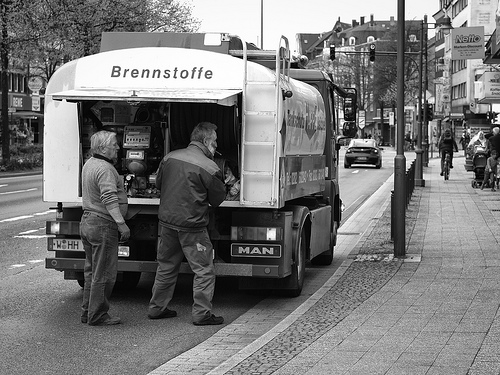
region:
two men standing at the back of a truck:
[24, 20, 368, 332]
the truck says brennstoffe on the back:
[25, 15, 357, 316]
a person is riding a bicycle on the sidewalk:
[429, 121, 467, 184]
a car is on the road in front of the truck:
[328, 115, 403, 187]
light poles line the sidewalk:
[382, 2, 452, 264]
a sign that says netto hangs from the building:
[423, 11, 499, 71]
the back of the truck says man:
[224, 202, 303, 286]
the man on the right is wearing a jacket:
[144, 119, 259, 339]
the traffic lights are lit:
[305, 36, 427, 71]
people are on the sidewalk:
[454, 120, 499, 221]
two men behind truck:
[24, 17, 372, 339]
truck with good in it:
[34, 7, 374, 324]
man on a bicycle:
[407, 119, 463, 192]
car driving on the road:
[337, 117, 394, 181]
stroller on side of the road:
[457, 133, 498, 193]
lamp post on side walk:
[377, 2, 417, 269]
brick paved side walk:
[221, 140, 498, 374]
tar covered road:
[4, 33, 428, 373]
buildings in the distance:
[297, 5, 453, 147]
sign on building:
[440, 14, 498, 77]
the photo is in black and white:
[2, 3, 497, 373]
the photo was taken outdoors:
[3, 3, 498, 370]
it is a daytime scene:
[1, 1, 495, 370]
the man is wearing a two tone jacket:
[148, 123, 235, 326]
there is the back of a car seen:
[341, 135, 387, 171]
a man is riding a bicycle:
[438, 128, 460, 183]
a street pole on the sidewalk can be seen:
[378, 0, 415, 258]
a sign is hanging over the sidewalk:
[448, 25, 487, 62]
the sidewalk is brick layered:
[211, 153, 498, 373]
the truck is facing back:
[31, 31, 338, 313]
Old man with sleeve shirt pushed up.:
[72, 123, 134, 338]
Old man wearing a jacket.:
[138, 113, 250, 325]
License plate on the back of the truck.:
[50, 238, 94, 251]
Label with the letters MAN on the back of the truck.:
[231, 240, 285, 258]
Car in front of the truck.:
[343, 130, 388, 175]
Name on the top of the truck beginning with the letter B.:
[96, 51, 226, 84]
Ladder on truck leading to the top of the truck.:
[233, 29, 305, 207]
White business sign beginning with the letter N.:
[448, 24, 490, 55]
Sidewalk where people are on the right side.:
[377, 154, 494, 369]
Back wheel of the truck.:
[281, 215, 310, 299]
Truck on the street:
[36, 31, 364, 238]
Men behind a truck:
[71, 120, 246, 355]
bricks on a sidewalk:
[385, 280, 480, 363]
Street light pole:
[386, 103, 419, 263]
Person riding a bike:
[439, 120, 471, 177]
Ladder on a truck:
[231, 35, 279, 198]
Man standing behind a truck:
[83, 134, 140, 314]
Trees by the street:
[8, 10, 111, 48]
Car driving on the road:
[346, 133, 378, 184]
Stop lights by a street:
[311, 41, 431, 73]